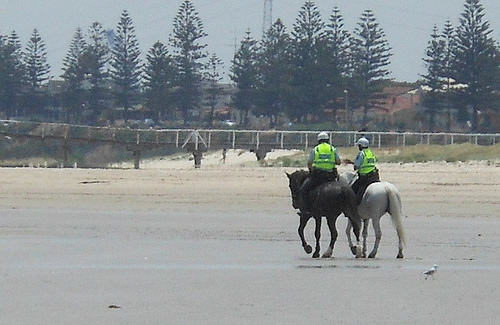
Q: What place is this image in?
A: It is at the beach.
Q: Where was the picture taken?
A: It was taken at the beach.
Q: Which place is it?
A: It is a beach.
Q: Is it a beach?
A: Yes, it is a beach.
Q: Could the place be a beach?
A: Yes, it is a beach.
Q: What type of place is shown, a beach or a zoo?
A: It is a beach.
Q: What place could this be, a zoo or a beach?
A: It is a beach.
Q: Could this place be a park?
A: No, it is a beach.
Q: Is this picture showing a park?
A: No, the picture is showing a beach.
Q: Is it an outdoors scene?
A: Yes, it is outdoors.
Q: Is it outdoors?
A: Yes, it is outdoors.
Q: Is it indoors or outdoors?
A: It is outdoors.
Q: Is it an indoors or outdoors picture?
A: It is outdoors.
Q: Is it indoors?
A: No, it is outdoors.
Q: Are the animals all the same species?
A: No, there are both horses and birds.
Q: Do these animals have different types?
A: Yes, they are horses and birds.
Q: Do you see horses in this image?
A: Yes, there is a horse.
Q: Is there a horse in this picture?
A: Yes, there is a horse.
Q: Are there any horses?
A: Yes, there is a horse.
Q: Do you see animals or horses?
A: Yes, there is a horse.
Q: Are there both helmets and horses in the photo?
A: Yes, there are both a horse and a helmet.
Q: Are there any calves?
A: No, there are no calves.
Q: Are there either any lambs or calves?
A: No, there are no calves or lambs.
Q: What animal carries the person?
A: The horse carries the person.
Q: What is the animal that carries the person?
A: The animal is a horse.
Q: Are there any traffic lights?
A: No, there are no traffic lights.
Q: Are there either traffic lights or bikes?
A: No, there are no traffic lights or bikes.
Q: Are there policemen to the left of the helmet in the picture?
A: Yes, there is a policeman to the left of the helmet.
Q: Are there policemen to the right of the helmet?
A: No, the policeman is to the left of the helmet.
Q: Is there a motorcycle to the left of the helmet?
A: No, there is a policeman to the left of the helmet.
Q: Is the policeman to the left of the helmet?
A: Yes, the policeman is to the left of the helmet.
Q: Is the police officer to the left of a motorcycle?
A: No, the police officer is to the left of the helmet.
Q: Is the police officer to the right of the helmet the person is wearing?
A: No, the police officer is to the left of the helmet.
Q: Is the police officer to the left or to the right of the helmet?
A: The police officer is to the left of the helmet.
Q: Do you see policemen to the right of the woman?
A: Yes, there is a policeman to the right of the woman.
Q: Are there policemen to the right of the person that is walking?
A: Yes, there is a policeman to the right of the woman.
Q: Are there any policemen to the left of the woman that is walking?
A: No, the policeman is to the right of the woman.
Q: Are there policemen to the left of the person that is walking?
A: No, the policeman is to the right of the woman.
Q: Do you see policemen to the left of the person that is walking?
A: No, the policeman is to the right of the woman.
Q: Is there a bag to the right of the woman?
A: No, there is a policeman to the right of the woman.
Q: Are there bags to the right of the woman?
A: No, there is a policeman to the right of the woman.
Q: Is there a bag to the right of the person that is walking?
A: No, there is a policeman to the right of the woman.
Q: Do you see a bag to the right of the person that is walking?
A: No, there is a policeman to the right of the woman.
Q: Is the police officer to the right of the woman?
A: Yes, the police officer is to the right of the woman.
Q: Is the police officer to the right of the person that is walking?
A: Yes, the police officer is to the right of the woman.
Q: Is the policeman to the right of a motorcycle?
A: No, the policeman is to the right of the woman.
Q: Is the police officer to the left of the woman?
A: No, the police officer is to the right of the woman.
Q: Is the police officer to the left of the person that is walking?
A: No, the police officer is to the right of the woman.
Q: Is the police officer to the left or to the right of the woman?
A: The police officer is to the right of the woman.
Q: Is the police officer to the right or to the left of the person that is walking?
A: The police officer is to the right of the woman.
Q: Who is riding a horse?
A: The policeman is riding a horse.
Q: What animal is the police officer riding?
A: The police officer is riding a horse.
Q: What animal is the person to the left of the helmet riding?
A: The police officer is riding a horse.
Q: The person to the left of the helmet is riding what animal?
A: The police officer is riding a horse.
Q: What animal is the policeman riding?
A: The police officer is riding a horse.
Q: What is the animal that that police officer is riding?
A: The animal is a horse.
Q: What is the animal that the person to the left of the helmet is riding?
A: The animal is a horse.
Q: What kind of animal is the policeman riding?
A: The police officer is riding a horse.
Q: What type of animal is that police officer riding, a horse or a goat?
A: The police officer is riding a horse.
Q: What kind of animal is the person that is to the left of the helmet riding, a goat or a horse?
A: The police officer is riding a horse.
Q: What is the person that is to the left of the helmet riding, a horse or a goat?
A: The police officer is riding a horse.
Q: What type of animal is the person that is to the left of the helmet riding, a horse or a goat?
A: The police officer is riding a horse.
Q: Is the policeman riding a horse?
A: Yes, the policeman is riding a horse.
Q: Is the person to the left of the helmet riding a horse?
A: Yes, the policeman is riding a horse.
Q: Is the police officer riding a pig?
A: No, the police officer is riding a horse.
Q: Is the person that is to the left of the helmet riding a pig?
A: No, the police officer is riding a horse.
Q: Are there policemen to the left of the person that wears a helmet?
A: Yes, there is a policeman to the left of the person.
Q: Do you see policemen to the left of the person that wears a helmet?
A: Yes, there is a policeman to the left of the person.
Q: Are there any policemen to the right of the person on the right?
A: No, the policeman is to the left of the person.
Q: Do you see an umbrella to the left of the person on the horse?
A: No, there is a policeman to the left of the person.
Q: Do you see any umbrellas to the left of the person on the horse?
A: No, there is a policeman to the left of the person.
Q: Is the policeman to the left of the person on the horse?
A: Yes, the policeman is to the left of the person.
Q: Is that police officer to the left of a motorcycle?
A: No, the police officer is to the left of the person.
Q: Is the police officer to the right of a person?
A: No, the police officer is to the left of a person.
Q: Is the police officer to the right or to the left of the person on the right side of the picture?
A: The police officer is to the left of the person.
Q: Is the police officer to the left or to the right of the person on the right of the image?
A: The police officer is to the left of the person.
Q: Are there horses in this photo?
A: Yes, there is a horse.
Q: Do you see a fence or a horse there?
A: Yes, there is a horse.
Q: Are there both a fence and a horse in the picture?
A: Yes, there are both a horse and a fence.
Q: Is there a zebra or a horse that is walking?
A: Yes, the horse is walking.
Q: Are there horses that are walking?
A: Yes, there is a horse that is walking.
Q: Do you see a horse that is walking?
A: Yes, there is a horse that is walking.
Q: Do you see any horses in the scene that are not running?
A: Yes, there is a horse that is walking .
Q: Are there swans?
A: No, there are no swans.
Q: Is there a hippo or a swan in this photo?
A: No, there are no swans or hippos.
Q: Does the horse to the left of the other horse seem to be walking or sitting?
A: The horse is walking.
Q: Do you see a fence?
A: Yes, there is a fence.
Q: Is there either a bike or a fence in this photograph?
A: Yes, there is a fence.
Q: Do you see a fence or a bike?
A: Yes, there is a fence.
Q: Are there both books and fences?
A: No, there is a fence but no books.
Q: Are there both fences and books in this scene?
A: No, there is a fence but no books.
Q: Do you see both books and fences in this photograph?
A: No, there is a fence but no books.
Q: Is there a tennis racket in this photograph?
A: No, there are no rackets.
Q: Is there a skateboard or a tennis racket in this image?
A: No, there are no rackets or skateboards.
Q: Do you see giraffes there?
A: No, there are no giraffes.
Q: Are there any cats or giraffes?
A: No, there are no giraffes or cats.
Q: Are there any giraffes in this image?
A: No, there are no giraffes.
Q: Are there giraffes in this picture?
A: No, there are no giraffes.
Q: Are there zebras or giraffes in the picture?
A: No, there are no giraffes or zebras.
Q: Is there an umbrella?
A: No, there are no umbrellas.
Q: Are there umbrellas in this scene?
A: No, there are no umbrellas.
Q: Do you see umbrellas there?
A: No, there are no umbrellas.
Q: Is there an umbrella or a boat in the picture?
A: No, there are no umbrellas or boats.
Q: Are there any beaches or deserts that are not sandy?
A: No, there is a beach but it is sandy.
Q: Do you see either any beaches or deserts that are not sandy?
A: No, there is a beach but it is sandy.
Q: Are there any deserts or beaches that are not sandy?
A: No, there is a beach but it is sandy.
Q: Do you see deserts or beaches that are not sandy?
A: No, there is a beach but it is sandy.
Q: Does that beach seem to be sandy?
A: Yes, the beach is sandy.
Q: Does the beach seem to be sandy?
A: Yes, the beach is sandy.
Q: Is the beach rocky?
A: No, the beach is sandy.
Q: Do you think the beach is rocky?
A: No, the beach is sandy.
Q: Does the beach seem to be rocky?
A: No, the beach is sandy.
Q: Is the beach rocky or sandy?
A: The beach is sandy.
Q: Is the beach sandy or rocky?
A: The beach is sandy.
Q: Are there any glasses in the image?
A: No, there are no glasses.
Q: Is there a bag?
A: No, there are no bags.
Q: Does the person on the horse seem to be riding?
A: Yes, the person is riding.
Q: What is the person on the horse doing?
A: The person is riding.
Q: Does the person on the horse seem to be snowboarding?
A: No, the person is riding.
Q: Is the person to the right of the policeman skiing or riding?
A: The person is riding.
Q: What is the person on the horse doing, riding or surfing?
A: The person is riding.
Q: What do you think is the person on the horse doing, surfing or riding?
A: The person is riding.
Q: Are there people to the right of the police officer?
A: Yes, there is a person to the right of the police officer.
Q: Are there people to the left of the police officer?
A: No, the person is to the right of the police officer.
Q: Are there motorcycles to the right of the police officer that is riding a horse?
A: No, there is a person to the right of the policeman.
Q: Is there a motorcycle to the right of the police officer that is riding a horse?
A: No, there is a person to the right of the policeman.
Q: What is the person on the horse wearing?
A: The person is wearing a helmet.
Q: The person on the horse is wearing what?
A: The person is wearing a helmet.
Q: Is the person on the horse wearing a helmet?
A: Yes, the person is wearing a helmet.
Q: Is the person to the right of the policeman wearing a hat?
A: No, the person is wearing a helmet.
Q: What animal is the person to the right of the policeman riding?
A: The person is riding a horse.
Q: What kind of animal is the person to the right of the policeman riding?
A: The person is riding a horse.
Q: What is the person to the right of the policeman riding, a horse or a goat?
A: The person is riding a horse.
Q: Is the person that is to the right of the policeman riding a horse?
A: Yes, the person is riding a horse.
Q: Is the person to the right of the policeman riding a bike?
A: No, the person is riding a horse.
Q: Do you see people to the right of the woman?
A: Yes, there is a person to the right of the woman.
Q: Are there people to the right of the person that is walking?
A: Yes, there is a person to the right of the woman.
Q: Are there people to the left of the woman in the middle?
A: No, the person is to the right of the woman.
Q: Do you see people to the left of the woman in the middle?
A: No, the person is to the right of the woman.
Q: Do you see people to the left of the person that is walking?
A: No, the person is to the right of the woman.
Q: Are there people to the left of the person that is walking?
A: No, the person is to the right of the woman.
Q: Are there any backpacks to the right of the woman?
A: No, there is a person to the right of the woman.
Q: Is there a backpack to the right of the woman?
A: No, there is a person to the right of the woman.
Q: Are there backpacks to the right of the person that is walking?
A: No, there is a person to the right of the woman.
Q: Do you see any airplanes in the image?
A: No, there are no airplanes.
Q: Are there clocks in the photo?
A: No, there are no clocks.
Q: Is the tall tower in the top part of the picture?
A: Yes, the tower is in the top of the image.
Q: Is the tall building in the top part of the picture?
A: Yes, the tower is in the top of the image.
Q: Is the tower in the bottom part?
A: No, the tower is in the top of the image.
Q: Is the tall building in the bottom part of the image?
A: No, the tower is in the top of the image.